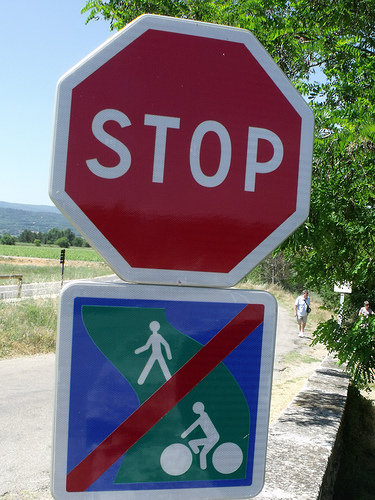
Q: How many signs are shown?
A: Two.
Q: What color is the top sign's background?
A: Red.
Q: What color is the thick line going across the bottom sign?
A: Red.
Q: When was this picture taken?
A: Daytime.